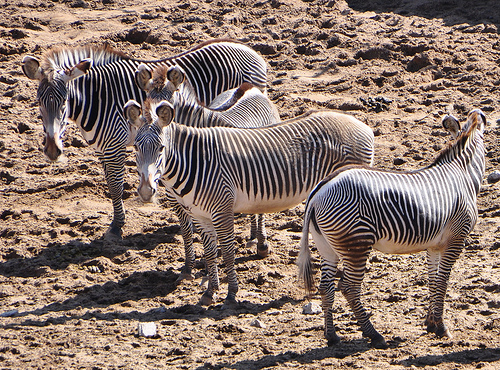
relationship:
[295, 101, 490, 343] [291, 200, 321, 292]
zebra has tail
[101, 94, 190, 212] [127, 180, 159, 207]
face with nose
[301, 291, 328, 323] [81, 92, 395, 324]
rock close to a zebra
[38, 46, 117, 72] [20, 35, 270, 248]
mane on zebra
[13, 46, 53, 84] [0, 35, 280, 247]
ear on zebra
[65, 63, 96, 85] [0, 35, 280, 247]
ear on zebra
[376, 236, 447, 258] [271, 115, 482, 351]
belly on zebra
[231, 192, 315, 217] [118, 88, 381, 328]
belly on zebra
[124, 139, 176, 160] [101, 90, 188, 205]
eyes on head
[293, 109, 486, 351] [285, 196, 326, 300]
zebra with tail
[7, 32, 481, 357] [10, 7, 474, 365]
zebras standing on ground